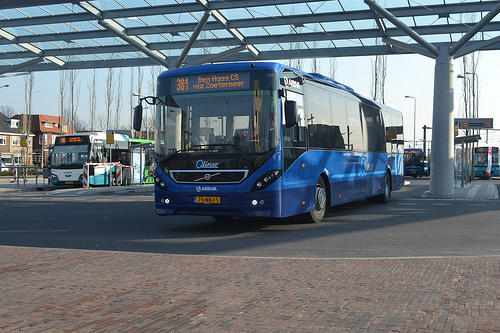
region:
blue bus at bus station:
[129, 62, 421, 224]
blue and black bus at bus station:
[140, 56, 412, 223]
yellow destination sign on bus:
[174, 72, 253, 92]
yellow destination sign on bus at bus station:
[156, 68, 262, 95]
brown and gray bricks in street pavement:
[14, 291, 79, 317]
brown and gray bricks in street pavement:
[102, 259, 161, 292]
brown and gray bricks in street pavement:
[22, 275, 90, 296]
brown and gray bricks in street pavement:
[224, 283, 286, 310]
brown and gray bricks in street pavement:
[317, 269, 379, 301]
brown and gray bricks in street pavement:
[389, 274, 456, 299]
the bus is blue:
[144, 59, 412, 229]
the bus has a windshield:
[147, 87, 284, 174]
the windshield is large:
[146, 91, 286, 158]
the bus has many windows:
[293, 75, 394, 157]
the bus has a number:
[172, 70, 190, 95]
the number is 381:
[170, 73, 192, 95]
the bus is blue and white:
[43, 127, 135, 189]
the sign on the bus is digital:
[169, 70, 256, 100]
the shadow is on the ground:
[1, 183, 498, 258]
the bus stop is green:
[128, 136, 157, 188]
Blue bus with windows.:
[145, 71, 413, 220]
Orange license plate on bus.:
[183, 190, 233, 207]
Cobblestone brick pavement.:
[165, 255, 372, 332]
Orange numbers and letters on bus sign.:
[170, 71, 255, 94]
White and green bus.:
[47, 132, 134, 188]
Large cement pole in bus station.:
[386, 5, 498, 206]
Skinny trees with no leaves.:
[57, 73, 135, 128]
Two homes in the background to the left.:
[0, 109, 59, 186]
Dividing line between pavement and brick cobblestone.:
[287, 238, 498, 278]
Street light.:
[399, 88, 421, 149]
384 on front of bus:
[167, 72, 192, 95]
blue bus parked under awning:
[133, 57, 415, 230]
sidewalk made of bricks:
[1, 243, 499, 330]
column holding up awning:
[423, 42, 465, 198]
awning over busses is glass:
[0, 0, 499, 75]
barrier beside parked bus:
[78, 155, 127, 190]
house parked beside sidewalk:
[13, 108, 80, 181]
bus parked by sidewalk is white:
[43, 120, 141, 192]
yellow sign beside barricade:
[101, 128, 121, 188]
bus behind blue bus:
[398, 142, 432, 179]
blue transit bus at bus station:
[146, 55, 411, 229]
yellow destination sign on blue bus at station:
[163, 74, 264, 97]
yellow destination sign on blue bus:
[174, 71, 261, 90]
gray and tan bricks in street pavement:
[8, 263, 85, 300]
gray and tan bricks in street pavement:
[124, 271, 221, 299]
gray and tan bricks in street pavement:
[216, 301, 268, 318]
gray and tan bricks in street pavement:
[259, 264, 339, 289]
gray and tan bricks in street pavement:
[321, 275, 386, 300]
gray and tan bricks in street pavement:
[393, 299, 478, 322]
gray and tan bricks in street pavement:
[384, 257, 466, 291]